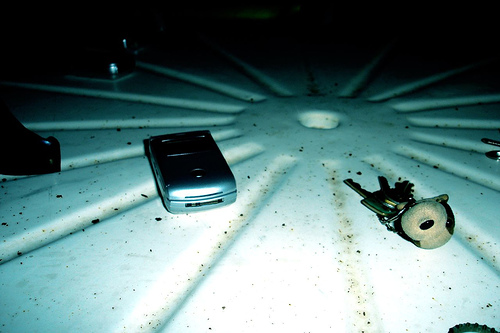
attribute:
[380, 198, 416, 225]
ring — silver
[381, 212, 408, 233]
ring — silver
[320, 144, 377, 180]
specks — brown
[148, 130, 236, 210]
cellphone — gray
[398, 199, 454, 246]
keychain — round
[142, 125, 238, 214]
phone — closed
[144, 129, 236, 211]
cell phone — silver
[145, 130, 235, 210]
phone — metallic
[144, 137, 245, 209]
cellphone — grey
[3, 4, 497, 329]
table — white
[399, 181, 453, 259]
ring — flat